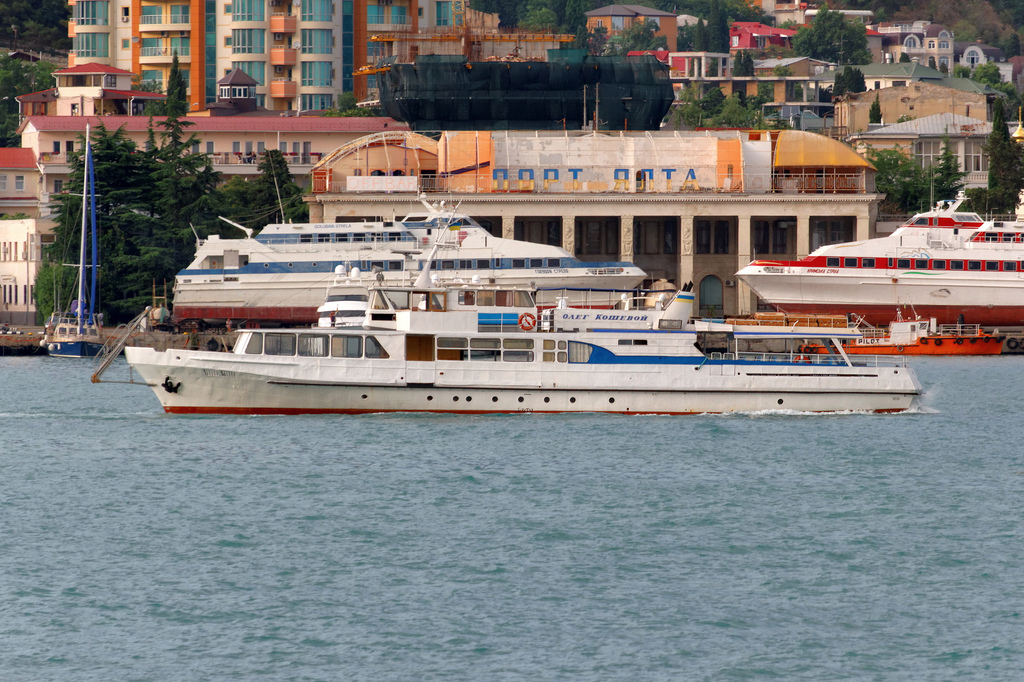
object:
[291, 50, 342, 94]
window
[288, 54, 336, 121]
window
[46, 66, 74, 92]
window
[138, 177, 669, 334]
yacht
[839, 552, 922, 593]
ripples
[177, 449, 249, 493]
ripples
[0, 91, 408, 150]
roof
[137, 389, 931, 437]
bottom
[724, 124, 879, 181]
roof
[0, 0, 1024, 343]
building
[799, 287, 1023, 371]
boat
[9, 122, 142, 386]
boat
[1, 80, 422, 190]
house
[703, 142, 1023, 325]
boat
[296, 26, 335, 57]
window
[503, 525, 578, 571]
ripples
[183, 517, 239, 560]
ripples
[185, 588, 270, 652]
ripples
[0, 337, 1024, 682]
water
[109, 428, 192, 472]
ripples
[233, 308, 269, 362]
window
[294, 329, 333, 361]
window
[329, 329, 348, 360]
window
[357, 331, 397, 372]
window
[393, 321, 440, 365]
window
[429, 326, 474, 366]
window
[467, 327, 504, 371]
window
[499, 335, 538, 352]
window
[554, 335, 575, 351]
window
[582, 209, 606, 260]
windows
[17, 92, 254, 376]
tree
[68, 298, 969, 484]
boat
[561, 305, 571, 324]
letters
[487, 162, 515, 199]
letters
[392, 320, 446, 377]
window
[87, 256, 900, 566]
boat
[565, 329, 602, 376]
window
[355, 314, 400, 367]
window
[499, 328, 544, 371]
window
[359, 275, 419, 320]
window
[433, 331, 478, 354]
window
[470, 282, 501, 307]
window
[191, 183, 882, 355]
boat